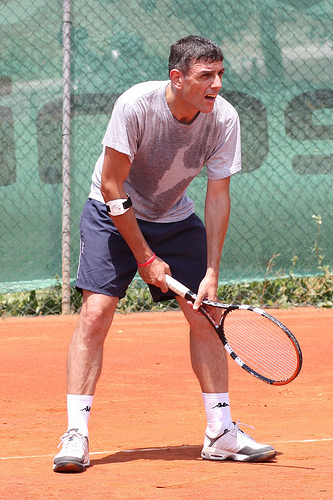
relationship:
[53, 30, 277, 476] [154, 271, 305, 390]
tennis player has tennis racket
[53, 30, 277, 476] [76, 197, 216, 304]
tennis player has shorts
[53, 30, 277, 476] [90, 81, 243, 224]
tennis player has t-shirt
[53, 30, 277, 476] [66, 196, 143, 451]
tennis player has leg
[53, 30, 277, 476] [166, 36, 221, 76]
tennis player has hair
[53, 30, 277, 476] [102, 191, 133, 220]
tennis player has wrist band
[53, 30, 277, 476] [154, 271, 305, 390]
tennis player holding tennis racket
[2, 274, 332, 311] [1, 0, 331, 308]
plants by fence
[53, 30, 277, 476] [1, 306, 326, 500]
tennis player playing on court